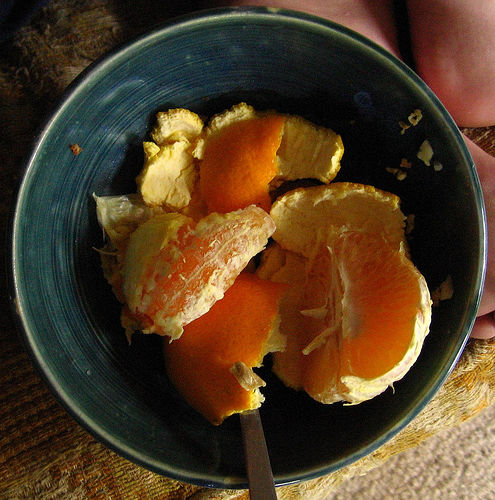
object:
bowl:
[0, 3, 495, 497]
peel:
[163, 272, 282, 421]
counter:
[0, 439, 106, 500]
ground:
[316, 402, 494, 500]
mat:
[0, 439, 98, 500]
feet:
[398, 0, 494, 129]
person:
[246, 0, 495, 348]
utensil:
[233, 408, 283, 500]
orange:
[273, 237, 439, 413]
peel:
[194, 104, 289, 214]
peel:
[261, 174, 409, 263]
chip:
[414, 132, 440, 174]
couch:
[0, 0, 495, 496]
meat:
[103, 196, 278, 339]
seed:
[300, 323, 339, 358]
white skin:
[123, 208, 185, 273]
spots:
[403, 107, 427, 131]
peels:
[130, 134, 204, 208]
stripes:
[0, 376, 57, 416]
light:
[473, 198, 494, 290]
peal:
[287, 117, 345, 181]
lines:
[68, 167, 96, 335]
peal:
[144, 103, 207, 144]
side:
[104, 5, 386, 57]